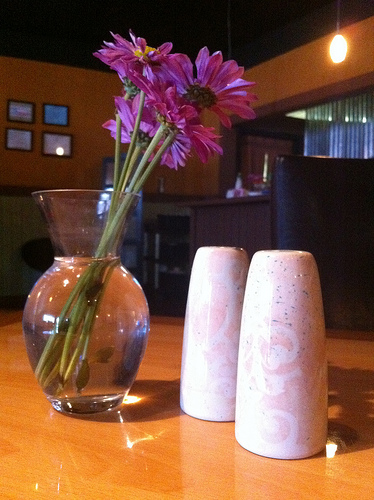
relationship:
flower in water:
[145, 86, 226, 162] [20, 254, 149, 416]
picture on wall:
[40, 103, 71, 127] [0, 56, 201, 309]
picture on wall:
[40, 127, 74, 157] [0, 56, 201, 309]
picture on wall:
[6, 99, 35, 123] [0, 56, 201, 309]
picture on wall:
[3, 125, 34, 153] [0, 56, 201, 309]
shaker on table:
[239, 247, 328, 471] [0, 292, 370, 497]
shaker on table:
[174, 243, 249, 423] [0, 292, 370, 497]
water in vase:
[102, 278, 140, 313] [20, 181, 154, 419]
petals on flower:
[188, 130, 208, 161] [32, 27, 256, 391]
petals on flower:
[207, 99, 230, 129] [32, 27, 256, 391]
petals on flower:
[193, 45, 209, 80] [32, 27, 256, 391]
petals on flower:
[166, 51, 192, 85] [32, 27, 256, 391]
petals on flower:
[215, 97, 253, 119] [32, 27, 256, 391]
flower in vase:
[145, 86, 226, 162] [49, 212, 140, 389]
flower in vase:
[145, 86, 226, 162] [20, 181, 154, 419]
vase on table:
[22, 188, 150, 417] [0, 292, 370, 497]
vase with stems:
[50, 211, 173, 389] [89, 138, 184, 225]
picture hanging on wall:
[42, 101, 70, 126] [0, 50, 238, 193]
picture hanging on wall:
[42, 128, 73, 158] [0, 50, 238, 193]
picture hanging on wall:
[6, 99, 35, 124] [0, 50, 238, 193]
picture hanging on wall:
[4, 125, 34, 152] [0, 50, 238, 193]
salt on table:
[172, 244, 248, 425] [0, 292, 370, 497]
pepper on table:
[231, 248, 328, 460] [0, 292, 370, 497]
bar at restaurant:
[135, 132, 372, 332] [0, 0, 373, 499]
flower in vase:
[145, 86, 226, 162] [22, 195, 133, 345]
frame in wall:
[35, 122, 78, 167] [0, 59, 180, 257]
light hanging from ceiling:
[326, 1, 349, 65] [4, 0, 369, 91]